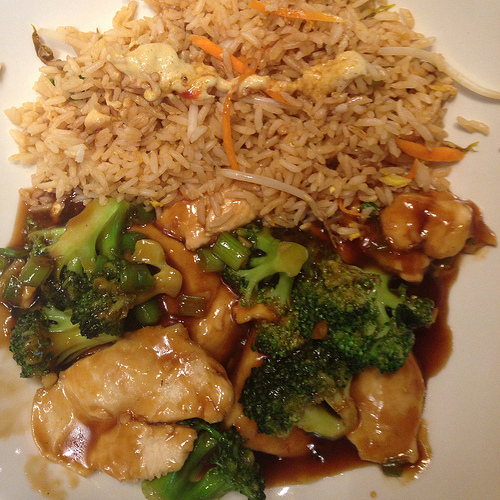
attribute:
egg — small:
[378, 172, 413, 191]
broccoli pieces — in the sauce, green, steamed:
[3, 198, 163, 374]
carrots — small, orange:
[189, 30, 295, 167]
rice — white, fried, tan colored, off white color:
[7, 3, 486, 226]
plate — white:
[1, 1, 500, 499]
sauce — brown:
[3, 190, 497, 498]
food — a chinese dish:
[3, 1, 500, 497]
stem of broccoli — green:
[60, 196, 120, 246]